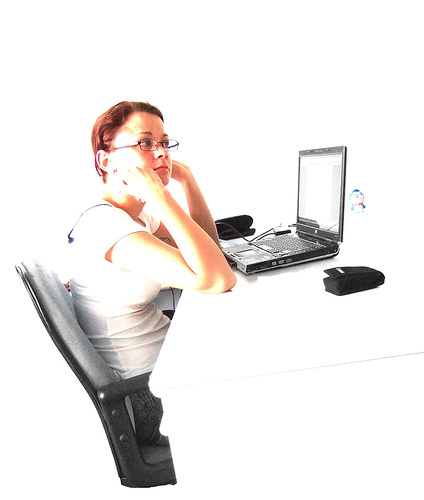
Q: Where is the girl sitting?
A: Desk.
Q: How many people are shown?
A: One.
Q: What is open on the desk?
A: Laptop.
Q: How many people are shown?
A: One.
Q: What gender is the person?
A: Female.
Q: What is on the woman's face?
A: Glasses.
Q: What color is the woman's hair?
A: Red.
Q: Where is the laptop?
A: Desk.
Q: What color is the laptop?
A: Black.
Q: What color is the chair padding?
A: Gray.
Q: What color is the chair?
A: Black.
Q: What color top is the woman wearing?
A: White.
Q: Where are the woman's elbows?
A: Desk.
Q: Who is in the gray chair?
A: Woman in the glasses.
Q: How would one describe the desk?
A: White.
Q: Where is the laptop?
A: On the desk.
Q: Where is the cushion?
A: On the chair.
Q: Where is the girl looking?
A: To her right.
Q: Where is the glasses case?
A: Left of the laptop.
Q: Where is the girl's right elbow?
A: On the desk.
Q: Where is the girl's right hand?
A: Touching her cheek.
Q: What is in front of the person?
A: Laptop.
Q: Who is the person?
A: A woman.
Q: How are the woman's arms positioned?
A: Bent.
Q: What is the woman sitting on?
A: Chair.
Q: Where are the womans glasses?
A: On her face.